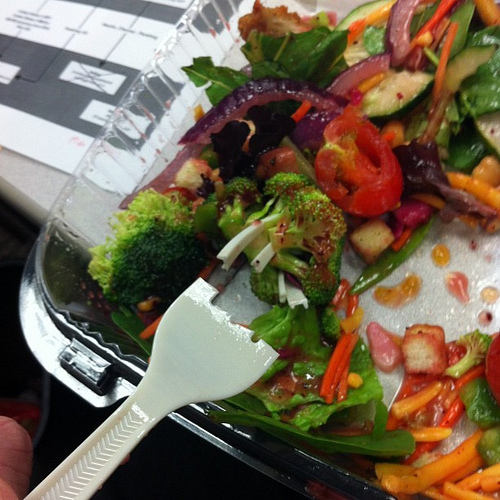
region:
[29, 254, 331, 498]
this is a fork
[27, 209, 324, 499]
the fork is plastic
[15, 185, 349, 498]
the fork is broken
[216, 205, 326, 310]
the prongs snapped off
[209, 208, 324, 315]
the prongs of the fork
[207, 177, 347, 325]
the prongs of the fork are in the broccoli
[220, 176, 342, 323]
a broccoli floret with the plastic fork prongs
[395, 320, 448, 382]
this is a crouton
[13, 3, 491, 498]
this is a plastic container with a salad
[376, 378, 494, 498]
this is cheddar cheese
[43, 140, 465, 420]
a bowl of food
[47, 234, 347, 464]
a white fork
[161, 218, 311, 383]
a broken fork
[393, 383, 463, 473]
carrots in the bowl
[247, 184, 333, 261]
a piece of broccoli on the bowl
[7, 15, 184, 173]
a piece of paper on the table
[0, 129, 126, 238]
a table under the food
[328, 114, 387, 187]
a tomato in the food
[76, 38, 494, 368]
vegetables in the bowl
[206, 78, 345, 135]
an onion on the food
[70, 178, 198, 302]
food in a tray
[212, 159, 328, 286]
food in a tray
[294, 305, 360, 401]
food in a tray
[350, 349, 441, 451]
food in a tray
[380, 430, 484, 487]
food in a tray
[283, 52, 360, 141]
food in a tray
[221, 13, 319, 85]
food in a tray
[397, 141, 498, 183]
food in a tray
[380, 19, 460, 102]
food in a tray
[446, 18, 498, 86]
food in a tray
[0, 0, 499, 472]
a gray desk top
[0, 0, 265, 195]
a paper on the desk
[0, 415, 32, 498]
a person holding a fork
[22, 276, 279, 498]
a white plastic fork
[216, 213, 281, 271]
a broken piece of the fork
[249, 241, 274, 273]
a broken piece of the fork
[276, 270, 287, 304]
a broken piece of the fork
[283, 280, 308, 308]
a broken piece of the fork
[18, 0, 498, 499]
a clear plastic container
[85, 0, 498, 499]
a salad in the container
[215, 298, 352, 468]
this is some salad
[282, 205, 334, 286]
this is some vinegarette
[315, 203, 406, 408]
the dressing is pink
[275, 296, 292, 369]
the dressing is raspberry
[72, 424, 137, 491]
this is a chevron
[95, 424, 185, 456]
this is a fork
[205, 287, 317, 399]
this is a broken fork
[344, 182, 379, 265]
this is a pepper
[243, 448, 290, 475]
this is a plastic container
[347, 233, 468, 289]
this is a crouton